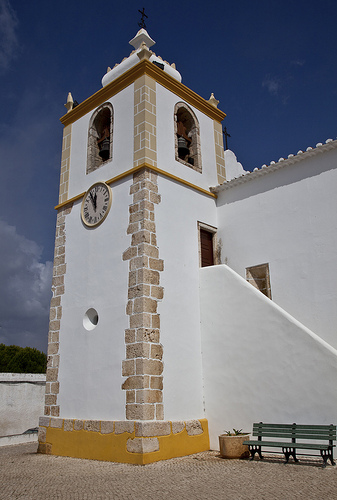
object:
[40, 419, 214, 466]
foundation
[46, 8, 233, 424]
tower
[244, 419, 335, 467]
bench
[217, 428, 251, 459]
planter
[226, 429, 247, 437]
plants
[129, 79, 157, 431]
brick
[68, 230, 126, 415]
stucco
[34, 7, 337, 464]
church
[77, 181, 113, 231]
clock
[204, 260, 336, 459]
stairway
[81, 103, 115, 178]
window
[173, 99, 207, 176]
window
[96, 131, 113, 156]
bell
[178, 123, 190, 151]
bell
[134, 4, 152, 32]
cross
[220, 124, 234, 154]
cross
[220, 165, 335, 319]
wall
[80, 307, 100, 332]
window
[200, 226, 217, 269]
door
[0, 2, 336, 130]
sky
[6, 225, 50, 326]
cloud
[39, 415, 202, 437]
brick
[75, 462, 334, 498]
ground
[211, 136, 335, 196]
roof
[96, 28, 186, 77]
steeple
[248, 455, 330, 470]
shadow